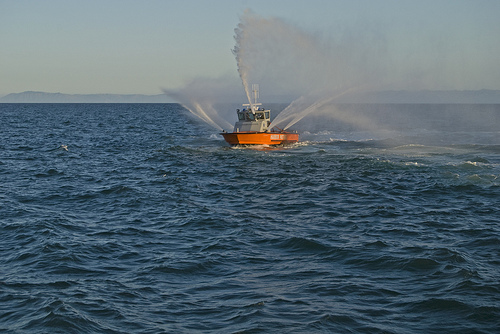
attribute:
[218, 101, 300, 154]
boat — orange, white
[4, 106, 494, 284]
water — blue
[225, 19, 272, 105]
water — spraying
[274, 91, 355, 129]
water — spraying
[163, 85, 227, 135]
water — spraying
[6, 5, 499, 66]
sky — blue, clear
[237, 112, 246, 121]
window — small, glass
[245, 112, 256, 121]
window — small, glass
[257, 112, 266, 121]
window — small, glass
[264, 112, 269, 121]
window — small, glass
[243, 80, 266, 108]
antenna — white, tall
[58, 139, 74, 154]
bird — flying, white, small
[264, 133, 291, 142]
words — white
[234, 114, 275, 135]
cabin — white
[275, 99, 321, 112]
water — spraying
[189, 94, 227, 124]
water — spraying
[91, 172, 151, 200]
waves — small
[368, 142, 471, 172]
waves — small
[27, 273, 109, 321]
waves — small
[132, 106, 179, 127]
waves — small